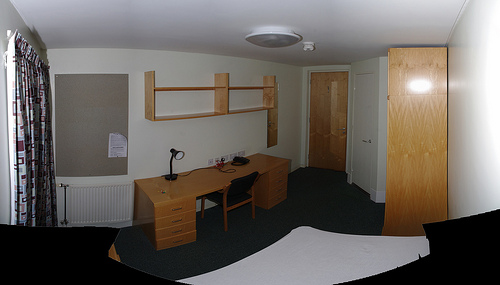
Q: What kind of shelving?
A: Wood.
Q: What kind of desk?
A: Wooden.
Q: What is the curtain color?
A: Blue.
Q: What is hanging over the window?
A: Curtains.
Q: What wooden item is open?
A: The door.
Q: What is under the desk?
A: Rug.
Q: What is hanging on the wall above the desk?
A: Shelves.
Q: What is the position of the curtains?
A: Closed.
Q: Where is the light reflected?
A: On the back of the door.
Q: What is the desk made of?
A: Wood.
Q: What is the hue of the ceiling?
A: White.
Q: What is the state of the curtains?
A: Closed.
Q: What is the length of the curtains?
A: Floor length.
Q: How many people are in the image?
A: No people in the image.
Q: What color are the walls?
A: White.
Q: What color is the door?
A: Brown.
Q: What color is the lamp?
A: Black.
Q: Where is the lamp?
A: On the desk.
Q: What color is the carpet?
A: Blue.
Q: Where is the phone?
A: Sitting on the desk.